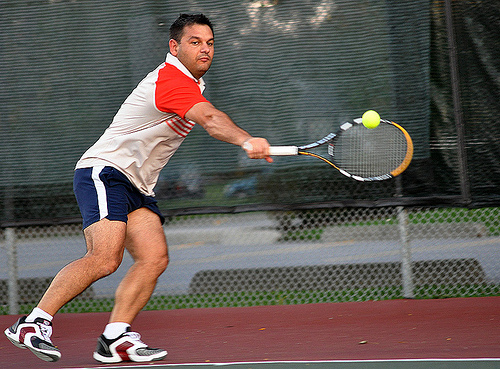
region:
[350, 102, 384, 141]
round yellow tennis ball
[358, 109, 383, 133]
round yellow tennis ball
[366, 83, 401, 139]
Green tennis ball in mid air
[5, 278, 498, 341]
Red surface of tennis court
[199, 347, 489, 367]
Green surface of tennis court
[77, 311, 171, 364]
White, red, and black sneaker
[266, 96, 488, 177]
Tennis racket about to hit ball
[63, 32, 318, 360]
Hispanic man playing tennis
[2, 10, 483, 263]
Green mesh hanging from fence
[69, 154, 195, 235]
Blue athletic shorts with white stripe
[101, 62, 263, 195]
Red and white polo shirt on man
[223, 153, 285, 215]
Teal vehicle in background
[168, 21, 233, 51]
Man has short hair.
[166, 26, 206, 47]
Man has dark hair.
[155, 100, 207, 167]
Man wearing white and red shirt.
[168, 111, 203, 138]
Red stripes on shirt.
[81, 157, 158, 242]
Man wearing blue shorts.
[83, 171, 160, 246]
White stripe on side of shorts.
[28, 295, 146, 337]
Man wearing white socks.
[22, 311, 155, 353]
Man wearing red, white, gray, and black shoes.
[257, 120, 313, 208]
Grip on racket is white.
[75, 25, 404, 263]
Man is playing tennis.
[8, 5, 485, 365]
tennis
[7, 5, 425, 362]
a man playing tennis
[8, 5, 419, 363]
a man holding a tennis racket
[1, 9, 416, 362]
a man is hitting a tennis ball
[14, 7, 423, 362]
the man is playing tennis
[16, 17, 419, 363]
the tennis player is hitting the ball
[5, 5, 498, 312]
a fence behind the player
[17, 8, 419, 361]
the man is swinging a tennis racket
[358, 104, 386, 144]
the ball is in the air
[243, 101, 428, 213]
the racket is about to hit the ball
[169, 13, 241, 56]
Person has dark hair.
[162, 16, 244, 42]
Person has short hair.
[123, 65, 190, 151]
Person has red and white shirt.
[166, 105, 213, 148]
Red stripes on shirt.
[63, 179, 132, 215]
Person wearing blue shorts.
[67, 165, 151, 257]
White stripe on shorts.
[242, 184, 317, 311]
Fence behind man playing tennis.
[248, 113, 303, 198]
Grip is white on racket.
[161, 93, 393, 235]
Man playing tennis.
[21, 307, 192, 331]
Man wearing white socks.